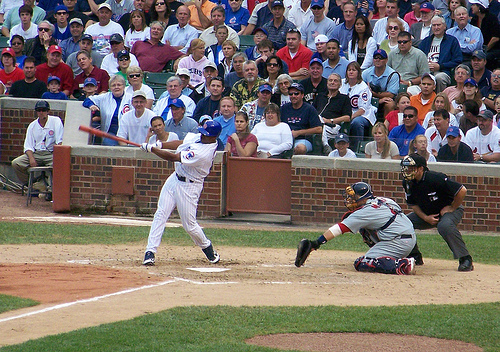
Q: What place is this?
A: It is a stadium.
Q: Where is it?
A: This is at the stadium.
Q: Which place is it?
A: It is a stadium.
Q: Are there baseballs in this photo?
A: Yes, there is a baseball.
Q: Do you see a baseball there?
A: Yes, there is a baseball.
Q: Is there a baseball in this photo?
A: Yes, there is a baseball.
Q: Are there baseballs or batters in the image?
A: Yes, there is a baseball.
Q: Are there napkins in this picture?
A: No, there are no napkins.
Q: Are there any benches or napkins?
A: No, there are no napkins or benches.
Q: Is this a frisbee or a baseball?
A: This is a baseball.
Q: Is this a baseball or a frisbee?
A: This is a baseball.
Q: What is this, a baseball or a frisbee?
A: This is a baseball.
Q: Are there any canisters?
A: No, there are no canisters.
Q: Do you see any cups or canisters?
A: No, there are no canisters or cups.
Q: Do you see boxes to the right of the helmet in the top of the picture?
A: Yes, there is a box to the right of the helmet.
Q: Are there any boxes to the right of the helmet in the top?
A: Yes, there is a box to the right of the helmet.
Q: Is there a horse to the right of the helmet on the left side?
A: No, there is a box to the right of the helmet.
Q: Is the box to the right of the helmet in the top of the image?
A: Yes, the box is to the right of the helmet.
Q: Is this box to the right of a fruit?
A: No, the box is to the right of the helmet.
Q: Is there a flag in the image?
A: No, there are no flags.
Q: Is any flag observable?
A: No, there are no flags.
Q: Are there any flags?
A: No, there are no flags.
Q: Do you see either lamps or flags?
A: No, there are no flags or lamps.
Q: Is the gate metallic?
A: Yes, the gate is metallic.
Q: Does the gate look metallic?
A: Yes, the gate is metallic.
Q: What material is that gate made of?
A: The gate is made of metal.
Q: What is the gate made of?
A: The gate is made of metal.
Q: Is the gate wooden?
A: No, the gate is metallic.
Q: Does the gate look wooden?
A: No, the gate is metallic.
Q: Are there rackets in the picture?
A: No, there are no rackets.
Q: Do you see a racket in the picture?
A: No, there are no rackets.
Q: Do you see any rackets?
A: No, there are no rackets.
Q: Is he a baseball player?
A: Yes, that is a baseball player.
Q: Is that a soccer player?
A: No, that is a baseball player.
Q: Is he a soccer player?
A: No, that is a baseball player.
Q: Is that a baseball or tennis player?
A: That is a baseball player.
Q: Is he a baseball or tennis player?
A: That is a baseball player.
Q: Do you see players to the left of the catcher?
A: Yes, there is a player to the left of the catcher.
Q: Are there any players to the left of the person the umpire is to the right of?
A: Yes, there is a player to the left of the catcher.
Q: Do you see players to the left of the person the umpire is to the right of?
A: Yes, there is a player to the left of the catcher.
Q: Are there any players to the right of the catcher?
A: No, the player is to the left of the catcher.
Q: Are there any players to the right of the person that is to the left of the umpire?
A: No, the player is to the left of the catcher.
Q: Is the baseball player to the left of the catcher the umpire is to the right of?
A: Yes, the player is to the left of the catcher.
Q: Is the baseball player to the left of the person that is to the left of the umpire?
A: Yes, the player is to the left of the catcher.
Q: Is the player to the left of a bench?
A: No, the player is to the left of the catcher.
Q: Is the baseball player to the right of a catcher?
A: No, the player is to the left of a catcher.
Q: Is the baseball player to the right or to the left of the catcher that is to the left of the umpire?
A: The player is to the left of the catcher.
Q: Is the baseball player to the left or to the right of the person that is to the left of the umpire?
A: The player is to the left of the catcher.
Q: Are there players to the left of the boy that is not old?
A: Yes, there is a player to the left of the boy.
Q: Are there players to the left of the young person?
A: Yes, there is a player to the left of the boy.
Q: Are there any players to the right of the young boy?
A: No, the player is to the left of the boy.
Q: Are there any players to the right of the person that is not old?
A: No, the player is to the left of the boy.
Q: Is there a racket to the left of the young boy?
A: No, there is a player to the left of the boy.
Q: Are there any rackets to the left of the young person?
A: No, there is a player to the left of the boy.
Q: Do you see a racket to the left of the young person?
A: No, there is a player to the left of the boy.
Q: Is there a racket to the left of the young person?
A: No, there is a player to the left of the boy.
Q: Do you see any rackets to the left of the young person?
A: No, there is a player to the left of the boy.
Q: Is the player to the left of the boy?
A: Yes, the player is to the left of the boy.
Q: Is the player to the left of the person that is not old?
A: Yes, the player is to the left of the boy.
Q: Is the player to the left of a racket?
A: No, the player is to the left of the boy.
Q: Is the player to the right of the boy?
A: No, the player is to the left of the boy.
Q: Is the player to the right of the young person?
A: No, the player is to the left of the boy.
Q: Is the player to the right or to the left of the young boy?
A: The player is to the left of the boy.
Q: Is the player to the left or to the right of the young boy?
A: The player is to the left of the boy.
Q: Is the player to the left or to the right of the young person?
A: The player is to the left of the boy.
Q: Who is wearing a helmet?
A: The player is wearing a helmet.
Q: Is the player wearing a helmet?
A: Yes, the player is wearing a helmet.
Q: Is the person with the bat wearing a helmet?
A: Yes, the player is wearing a helmet.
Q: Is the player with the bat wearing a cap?
A: No, the player is wearing a helmet.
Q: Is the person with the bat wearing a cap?
A: No, the player is wearing a helmet.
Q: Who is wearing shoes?
A: The player is wearing shoes.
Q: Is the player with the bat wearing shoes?
A: Yes, the player is wearing shoes.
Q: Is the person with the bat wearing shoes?
A: Yes, the player is wearing shoes.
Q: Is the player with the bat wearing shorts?
A: No, the player is wearing shoes.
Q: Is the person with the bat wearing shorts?
A: No, the player is wearing shoes.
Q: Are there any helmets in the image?
A: Yes, there is a helmet.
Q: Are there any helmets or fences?
A: Yes, there is a helmet.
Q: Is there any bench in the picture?
A: No, there are no benches.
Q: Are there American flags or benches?
A: No, there are no benches or American flags.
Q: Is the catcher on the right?
A: Yes, the catcher is on the right of the image.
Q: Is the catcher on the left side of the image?
A: No, the catcher is on the right of the image.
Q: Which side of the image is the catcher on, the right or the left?
A: The catcher is on the right of the image.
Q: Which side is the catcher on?
A: The catcher is on the right of the image.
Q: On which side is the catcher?
A: The catcher is on the right of the image.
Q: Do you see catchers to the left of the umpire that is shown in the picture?
A: Yes, there is a catcher to the left of the umpire.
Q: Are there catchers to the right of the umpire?
A: No, the catcher is to the left of the umpire.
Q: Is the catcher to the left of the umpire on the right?
A: Yes, the catcher is to the left of the umpire.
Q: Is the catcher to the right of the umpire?
A: No, the catcher is to the left of the umpire.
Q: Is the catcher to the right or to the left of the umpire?
A: The catcher is to the left of the umpire.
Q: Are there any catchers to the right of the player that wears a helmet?
A: Yes, there is a catcher to the right of the player.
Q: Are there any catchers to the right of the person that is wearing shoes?
A: Yes, there is a catcher to the right of the player.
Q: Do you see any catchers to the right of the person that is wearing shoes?
A: Yes, there is a catcher to the right of the player.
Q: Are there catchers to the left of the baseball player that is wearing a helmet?
A: No, the catcher is to the right of the player.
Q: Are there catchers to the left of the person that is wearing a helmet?
A: No, the catcher is to the right of the player.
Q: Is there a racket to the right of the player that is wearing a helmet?
A: No, there is a catcher to the right of the player.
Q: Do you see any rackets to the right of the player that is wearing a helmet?
A: No, there is a catcher to the right of the player.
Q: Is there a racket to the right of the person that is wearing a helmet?
A: No, there is a catcher to the right of the player.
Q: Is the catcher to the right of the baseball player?
A: Yes, the catcher is to the right of the player.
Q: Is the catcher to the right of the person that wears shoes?
A: Yes, the catcher is to the right of the player.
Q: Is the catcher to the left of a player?
A: No, the catcher is to the right of a player.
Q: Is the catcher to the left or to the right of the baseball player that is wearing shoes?
A: The catcher is to the right of the player.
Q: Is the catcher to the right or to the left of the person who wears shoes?
A: The catcher is to the right of the player.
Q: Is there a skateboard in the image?
A: No, there are no skateboards.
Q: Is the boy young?
A: Yes, the boy is young.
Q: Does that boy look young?
A: Yes, the boy is young.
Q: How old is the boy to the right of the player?
A: The boy is young.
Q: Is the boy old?
A: No, the boy is young.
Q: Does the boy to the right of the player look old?
A: No, the boy is young.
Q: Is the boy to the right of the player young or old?
A: The boy is young.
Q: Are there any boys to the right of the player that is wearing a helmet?
A: Yes, there is a boy to the right of the player.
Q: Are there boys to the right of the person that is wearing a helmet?
A: Yes, there is a boy to the right of the player.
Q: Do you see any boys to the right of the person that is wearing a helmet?
A: Yes, there is a boy to the right of the player.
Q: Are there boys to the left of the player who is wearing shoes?
A: No, the boy is to the right of the player.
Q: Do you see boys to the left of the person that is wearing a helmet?
A: No, the boy is to the right of the player.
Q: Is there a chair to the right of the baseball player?
A: No, there is a boy to the right of the player.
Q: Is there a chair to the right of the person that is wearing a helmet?
A: No, there is a boy to the right of the player.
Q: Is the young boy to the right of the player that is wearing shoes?
A: Yes, the boy is to the right of the player.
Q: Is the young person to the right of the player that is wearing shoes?
A: Yes, the boy is to the right of the player.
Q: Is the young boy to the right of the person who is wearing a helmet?
A: Yes, the boy is to the right of the player.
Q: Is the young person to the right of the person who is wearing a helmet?
A: Yes, the boy is to the right of the player.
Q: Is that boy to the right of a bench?
A: No, the boy is to the right of the player.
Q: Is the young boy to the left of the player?
A: No, the boy is to the right of the player.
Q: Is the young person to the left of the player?
A: No, the boy is to the right of the player.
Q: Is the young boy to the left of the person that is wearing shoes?
A: No, the boy is to the right of the player.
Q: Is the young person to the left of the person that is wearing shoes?
A: No, the boy is to the right of the player.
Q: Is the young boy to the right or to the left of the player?
A: The boy is to the right of the player.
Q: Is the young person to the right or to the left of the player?
A: The boy is to the right of the player.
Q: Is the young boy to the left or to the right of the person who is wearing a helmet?
A: The boy is to the right of the player.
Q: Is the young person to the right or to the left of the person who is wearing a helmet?
A: The boy is to the right of the player.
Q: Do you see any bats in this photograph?
A: Yes, there is a bat.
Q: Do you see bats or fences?
A: Yes, there is a bat.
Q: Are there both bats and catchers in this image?
A: Yes, there are both a bat and a catcher.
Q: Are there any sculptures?
A: No, there are no sculptures.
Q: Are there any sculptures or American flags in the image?
A: No, there are no sculptures or American flags.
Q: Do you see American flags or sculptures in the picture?
A: No, there are no sculptures or American flags.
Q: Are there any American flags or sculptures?
A: No, there are no sculptures or American flags.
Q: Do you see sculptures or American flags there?
A: No, there are no sculptures or American flags.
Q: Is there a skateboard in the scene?
A: No, there are no skateboards.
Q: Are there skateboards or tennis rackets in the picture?
A: No, there are no skateboards or tennis rackets.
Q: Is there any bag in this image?
A: No, there are no bags.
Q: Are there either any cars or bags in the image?
A: No, there are no bags or cars.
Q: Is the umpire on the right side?
A: Yes, the umpire is on the right of the image.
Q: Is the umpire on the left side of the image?
A: No, the umpire is on the right of the image.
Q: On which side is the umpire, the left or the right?
A: The umpire is on the right of the image.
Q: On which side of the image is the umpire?
A: The umpire is on the right of the image.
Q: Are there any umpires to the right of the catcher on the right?
A: Yes, there is an umpire to the right of the catcher.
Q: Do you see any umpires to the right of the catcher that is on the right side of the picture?
A: Yes, there is an umpire to the right of the catcher.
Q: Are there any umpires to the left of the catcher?
A: No, the umpire is to the right of the catcher.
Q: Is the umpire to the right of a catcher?
A: Yes, the umpire is to the right of a catcher.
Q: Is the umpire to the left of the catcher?
A: No, the umpire is to the right of the catcher.